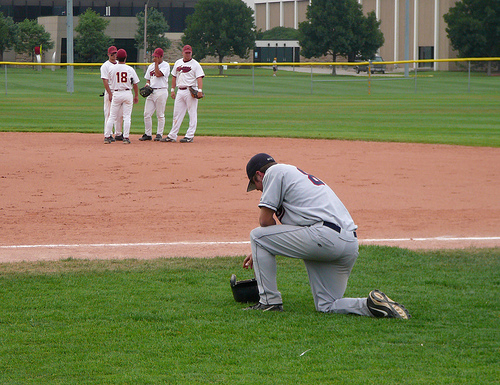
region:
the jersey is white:
[106, 62, 263, 117]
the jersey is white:
[100, 48, 157, 119]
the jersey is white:
[80, 52, 197, 143]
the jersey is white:
[100, 45, 285, 149]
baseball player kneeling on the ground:
[206, 148, 407, 346]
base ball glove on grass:
[220, 266, 276, 311]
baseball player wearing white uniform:
[110, 45, 140, 135]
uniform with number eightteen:
[115, 60, 140, 115]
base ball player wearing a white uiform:
[135, 40, 170, 140]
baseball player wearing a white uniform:
[165, 40, 215, 145]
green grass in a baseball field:
[245, 65, 485, 140]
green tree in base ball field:
[290, 0, 380, 65]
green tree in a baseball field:
[195, 5, 266, 66]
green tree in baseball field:
[72, 11, 114, 55]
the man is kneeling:
[228, 148, 415, 323]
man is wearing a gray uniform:
[221, 145, 410, 330]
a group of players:
[91, 37, 211, 148]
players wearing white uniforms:
[94, 37, 216, 149]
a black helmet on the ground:
[221, 258, 266, 312]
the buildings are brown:
[0, 0, 497, 77]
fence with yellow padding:
[0, 50, 497, 102]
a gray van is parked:
[347, 45, 391, 83]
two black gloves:
[134, 79, 204, 104]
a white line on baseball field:
[0, 227, 499, 252]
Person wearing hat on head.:
[241, 146, 303, 218]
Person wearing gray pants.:
[253, 224, 350, 303]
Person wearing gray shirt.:
[258, 164, 345, 247]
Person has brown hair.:
[247, 165, 287, 201]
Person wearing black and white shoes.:
[226, 282, 315, 348]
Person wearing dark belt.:
[328, 213, 349, 258]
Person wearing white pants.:
[103, 110, 131, 140]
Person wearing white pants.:
[168, 97, 223, 148]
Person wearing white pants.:
[131, 107, 175, 149]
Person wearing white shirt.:
[171, 65, 204, 83]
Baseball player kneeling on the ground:
[207, 142, 421, 327]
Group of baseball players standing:
[95, 39, 207, 152]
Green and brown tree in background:
[296, 2, 373, 80]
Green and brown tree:
[182, 8, 257, 73]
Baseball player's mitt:
[222, 266, 259, 316]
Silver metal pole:
[58, 5, 80, 92]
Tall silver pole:
[399, 2, 415, 80]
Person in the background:
[267, 53, 284, 80]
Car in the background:
[353, 49, 388, 79]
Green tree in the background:
[75, 9, 108, 66]